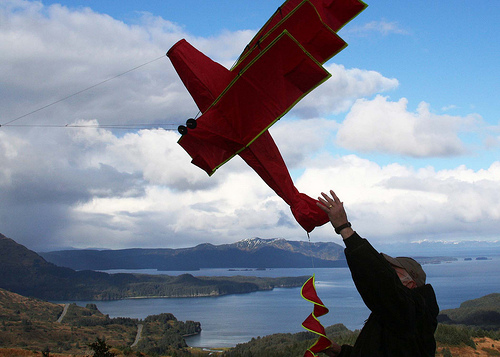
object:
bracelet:
[334, 221, 351, 234]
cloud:
[357, 106, 457, 155]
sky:
[371, 15, 426, 67]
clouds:
[13, 166, 159, 220]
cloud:
[451, 122, 498, 158]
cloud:
[2, 118, 62, 161]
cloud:
[0, 0, 118, 41]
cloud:
[449, 156, 499, 244]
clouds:
[283, 117, 306, 152]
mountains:
[0, 230, 346, 301]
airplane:
[165, 0, 368, 233]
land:
[32, 231, 490, 269]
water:
[46, 254, 499, 355]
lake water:
[186, 290, 310, 329]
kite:
[165, 0, 370, 356]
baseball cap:
[379, 252, 426, 287]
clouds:
[359, 159, 394, 212]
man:
[315, 189, 440, 356]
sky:
[426, 43, 475, 98]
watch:
[334, 221, 352, 234]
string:
[0, 122, 188, 131]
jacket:
[337, 230, 441, 356]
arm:
[336, 228, 403, 312]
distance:
[0, 1, 499, 238]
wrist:
[334, 220, 355, 235]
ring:
[328, 204, 333, 208]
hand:
[315, 189, 348, 229]